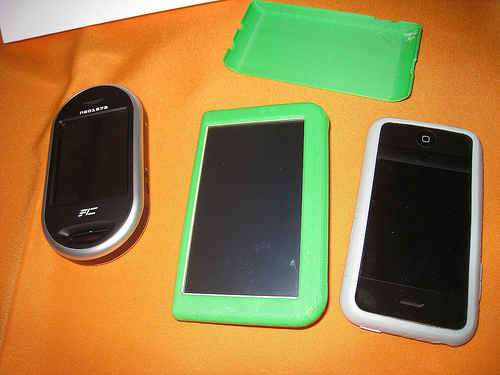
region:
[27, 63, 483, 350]
Three mobiles are on cloth.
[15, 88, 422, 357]
Cloth is orange color.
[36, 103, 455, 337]
Mobile screen is off.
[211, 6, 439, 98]
Mobile cover is green color.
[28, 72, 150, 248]
Mobile on left is grey color.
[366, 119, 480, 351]
Mobile on right is white color.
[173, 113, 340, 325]
Middle mobile is green color.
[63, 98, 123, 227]
Letters are white color.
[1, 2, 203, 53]
White paper near the mobile.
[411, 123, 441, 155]
Button is round shape.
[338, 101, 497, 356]
the phone's case is white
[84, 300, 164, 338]
the tablecloth is orange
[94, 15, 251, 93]
the tablecloth is orange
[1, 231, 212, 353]
the tablecloth is orange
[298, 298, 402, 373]
the tablecloth is orange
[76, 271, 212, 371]
the tablecloth is orange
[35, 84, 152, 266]
A black a silver cell phone.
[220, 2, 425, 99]
The back cover to a green case.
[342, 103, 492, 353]
A white and black Iphone.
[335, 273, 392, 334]
Finger print on the screen.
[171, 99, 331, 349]
A smart phone covered in green.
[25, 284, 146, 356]
Wooden table phones are on.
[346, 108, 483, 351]
Iphone with a white case.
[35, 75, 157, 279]
A very old cell phone.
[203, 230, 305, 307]
Smart phone dirty screen.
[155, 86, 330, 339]
Green case for smart phone.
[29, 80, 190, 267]
grey and black phone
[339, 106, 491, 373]
white and black phone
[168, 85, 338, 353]
green case on phone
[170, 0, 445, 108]
green back case of phone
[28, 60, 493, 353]
three phones on table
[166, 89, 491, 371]
two phones with case on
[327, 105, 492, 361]
white case on phone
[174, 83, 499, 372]
two phones on table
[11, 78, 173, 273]
one phone on table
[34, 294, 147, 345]
orange cloth under phones